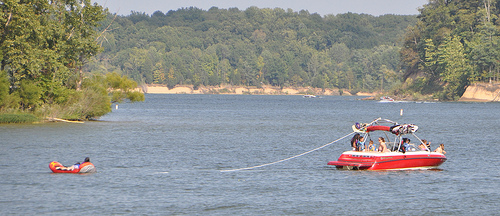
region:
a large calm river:
[134, 95, 441, 123]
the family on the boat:
[336, 119, 448, 169]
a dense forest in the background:
[116, 12, 498, 84]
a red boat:
[339, 142, 446, 168]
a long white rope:
[164, 139, 329, 169]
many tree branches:
[10, 13, 85, 94]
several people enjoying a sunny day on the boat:
[325, 114, 447, 172]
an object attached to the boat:
[50, 151, 92, 174]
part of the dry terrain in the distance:
[162, 85, 277, 92]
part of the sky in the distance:
[318, 2, 415, 15]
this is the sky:
[378, 2, 407, 9]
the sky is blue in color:
[363, 3, 397, 13]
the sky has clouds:
[384, 3, 396, 7]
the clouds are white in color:
[368, 1, 380, 6]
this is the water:
[186, 168, 253, 193]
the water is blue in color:
[183, 117, 238, 150]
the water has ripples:
[196, 115, 280, 177]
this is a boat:
[34, 121, 446, 186]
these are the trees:
[270, 35, 393, 91]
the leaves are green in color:
[47, 57, 79, 95]